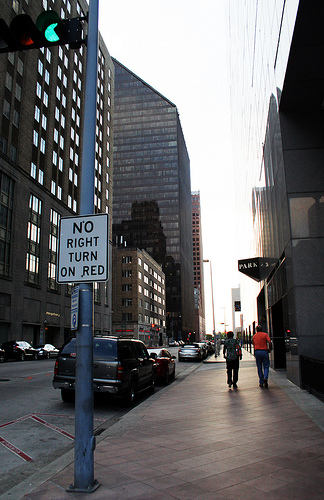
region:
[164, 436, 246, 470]
brick tiles on sidewalk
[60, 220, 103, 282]
sign on the pole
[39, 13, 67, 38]
green light on traffic signal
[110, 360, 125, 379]
light on back of car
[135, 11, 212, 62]
part of the sky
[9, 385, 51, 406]
part of the street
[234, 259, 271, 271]
park sign for garage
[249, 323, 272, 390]
man walking down street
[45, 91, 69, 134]
windows in the building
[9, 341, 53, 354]
cars parked on street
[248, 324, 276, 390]
man in orange shirt walking on sidewalk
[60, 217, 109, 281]
black and white traffic sign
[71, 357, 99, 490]
grey metal traffic signal pole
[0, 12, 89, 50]
traffic signal showing green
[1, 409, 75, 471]
red parking stripes on side of road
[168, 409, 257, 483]
brown tile on sidewalk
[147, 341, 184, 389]
red car parked beside road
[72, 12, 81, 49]
silver bolts securing traffic signal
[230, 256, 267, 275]
white writing on front of building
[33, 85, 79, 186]
side of building covered in windows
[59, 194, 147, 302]
Sign on the pole.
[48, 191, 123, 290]
White sign on the pole.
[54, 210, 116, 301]
White sign with black letters.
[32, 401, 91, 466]
Red stripes on the ground.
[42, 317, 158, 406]
SUV on the road.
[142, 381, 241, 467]
Sidewalk by the road.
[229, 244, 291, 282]
Park sign on the building.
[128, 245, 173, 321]
Windows on the building.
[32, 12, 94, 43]
Green light on the pole.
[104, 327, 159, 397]
Window on the SUV.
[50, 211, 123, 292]
black and white street sign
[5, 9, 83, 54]
traffic signal on left of pole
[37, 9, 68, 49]
lit green light on signal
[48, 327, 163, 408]
gray suv parked at curb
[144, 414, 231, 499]
red stone tile sidewalk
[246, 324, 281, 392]
back of man in red shirt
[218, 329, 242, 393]
back of man in flowered shirt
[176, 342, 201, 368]
back of silver car at curb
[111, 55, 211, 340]
multi-storied black sky scraper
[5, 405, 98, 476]
red No parking stripes on street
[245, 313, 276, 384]
Man in red shirt.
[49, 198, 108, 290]
Traffic sign on post.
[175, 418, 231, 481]
Diamond pattern walk way.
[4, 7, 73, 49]
Stop light on pole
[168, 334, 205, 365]
Silver convertible parked by curb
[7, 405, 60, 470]
Red no parking sign on street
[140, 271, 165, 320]
Windows on a multi unit building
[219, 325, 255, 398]
A woman walking on sidewalk.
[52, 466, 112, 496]
Bolts holding street pole.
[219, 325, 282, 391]
A couple walking on the sidewalk